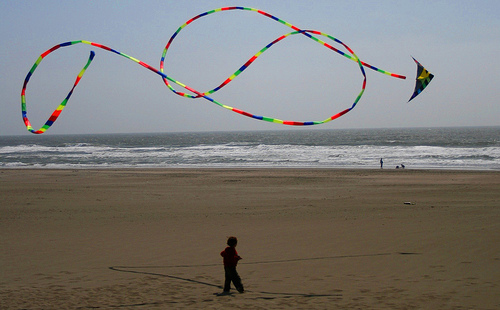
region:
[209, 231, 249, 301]
small boy flying kite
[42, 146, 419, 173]
white waves crashing in ocean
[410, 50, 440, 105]
arrow shaped kite overhead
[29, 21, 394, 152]
long rainbow colored tail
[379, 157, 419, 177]
group of people sitting by water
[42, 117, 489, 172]
gray ocean in the distance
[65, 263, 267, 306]
foot prints in the sand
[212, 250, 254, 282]
red hoodie on little boy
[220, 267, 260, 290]
baggy jeans on little boy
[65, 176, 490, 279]
smooth sand in front of boy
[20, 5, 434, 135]
A long kite in the sky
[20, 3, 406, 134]
A long colorful kite tail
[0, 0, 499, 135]
a clear blue sky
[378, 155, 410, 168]
a group of people on the beach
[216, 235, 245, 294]
A child on the ebach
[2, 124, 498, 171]
The ocean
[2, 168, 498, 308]
A sandy beach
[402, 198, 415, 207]
some trash on the beach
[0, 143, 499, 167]
some waves moving towards shore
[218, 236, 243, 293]
A child in a red shirt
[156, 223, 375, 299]
a child walking on sand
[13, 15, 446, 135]
a multicolored kite with a long tail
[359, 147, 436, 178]
people next to the shore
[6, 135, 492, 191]
waves washing on shore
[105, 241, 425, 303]
the shadow of the kite is on the sand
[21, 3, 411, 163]
a multicolored kite tail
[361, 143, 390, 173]
a person standing near the water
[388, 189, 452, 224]
litter on the sand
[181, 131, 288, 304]
a child at the beach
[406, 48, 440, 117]
a triangle shaped kite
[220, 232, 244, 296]
small child standing in sand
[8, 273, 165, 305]
several footprints are in the sand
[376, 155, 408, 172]
people are near the water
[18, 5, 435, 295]
child is flying a kite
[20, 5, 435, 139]
kite is flying in the air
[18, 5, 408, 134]
long colorful tail attached to kite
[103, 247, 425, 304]
shadow of kite on beach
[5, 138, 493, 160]
white capped ocean waves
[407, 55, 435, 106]
kite body is triangular shaped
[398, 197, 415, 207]
gray rock lying on sandy beach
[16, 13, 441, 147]
kite flying in the sky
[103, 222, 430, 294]
kite's shadow on the sand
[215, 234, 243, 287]
child standing on beach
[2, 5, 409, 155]
striped tail of kite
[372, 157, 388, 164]
person standing along water's edge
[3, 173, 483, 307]
sand child is standing on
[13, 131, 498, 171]
waves crashing in the ocean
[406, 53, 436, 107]
body of kite flying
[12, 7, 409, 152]
yellow stripes on kite's tail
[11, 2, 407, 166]
blue stripes on kite's tail